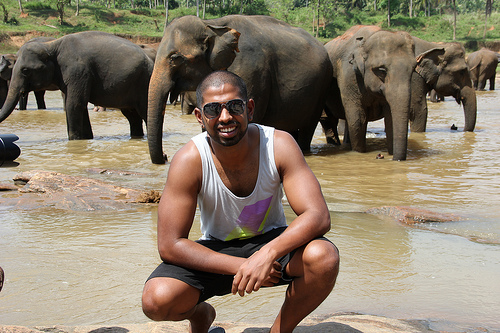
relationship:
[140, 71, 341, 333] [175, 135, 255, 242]
man in tank top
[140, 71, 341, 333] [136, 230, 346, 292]
man wearing shorts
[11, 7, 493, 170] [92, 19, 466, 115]
herd of elephants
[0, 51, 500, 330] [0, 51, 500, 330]
lake of lake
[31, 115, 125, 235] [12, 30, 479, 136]
bath hole for elephants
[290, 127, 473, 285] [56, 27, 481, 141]
watering hole for animals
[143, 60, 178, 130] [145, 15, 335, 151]
dirt on elephant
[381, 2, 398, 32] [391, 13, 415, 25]
tree has leaves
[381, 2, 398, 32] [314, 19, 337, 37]
tree has leaves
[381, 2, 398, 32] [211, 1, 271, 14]
tree has leaves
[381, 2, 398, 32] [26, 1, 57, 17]
tree has leaves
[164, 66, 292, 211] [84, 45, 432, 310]
man posing for picture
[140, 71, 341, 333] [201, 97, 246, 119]
man wears sunglasses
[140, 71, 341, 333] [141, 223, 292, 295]
man has shorts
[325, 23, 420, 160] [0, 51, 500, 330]
elephant in lake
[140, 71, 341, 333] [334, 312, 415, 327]
man in ground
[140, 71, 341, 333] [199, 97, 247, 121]
man in sunglasses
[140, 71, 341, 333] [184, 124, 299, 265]
man wearing tank top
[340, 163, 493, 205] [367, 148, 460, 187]
ripples in water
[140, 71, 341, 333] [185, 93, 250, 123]
man wearing sunglasses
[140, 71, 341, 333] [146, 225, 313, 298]
man in black shorts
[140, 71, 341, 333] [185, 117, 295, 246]
man wearing vest